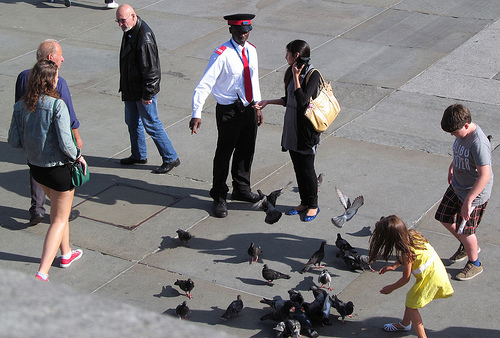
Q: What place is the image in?
A: It is at the city.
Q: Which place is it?
A: It is a city.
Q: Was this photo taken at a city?
A: Yes, it was taken in a city.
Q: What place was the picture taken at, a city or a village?
A: It was taken at a city.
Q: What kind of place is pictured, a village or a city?
A: It is a city.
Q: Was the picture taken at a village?
A: No, the picture was taken in a city.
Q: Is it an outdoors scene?
A: Yes, it is outdoors.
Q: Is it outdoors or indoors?
A: It is outdoors.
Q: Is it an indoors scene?
A: No, it is outdoors.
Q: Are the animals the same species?
A: No, there are both pigeons and birds.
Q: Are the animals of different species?
A: Yes, they are pigeons and birds.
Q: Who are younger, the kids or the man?
A: The kids are younger than the man.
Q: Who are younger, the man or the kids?
A: The kids are younger than the man.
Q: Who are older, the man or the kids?
A: The man are older than the kids.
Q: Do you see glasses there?
A: No, there are no glasses.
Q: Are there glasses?
A: No, there are no glasses.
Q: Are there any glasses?
A: No, there are no glasses.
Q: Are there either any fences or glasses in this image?
A: No, there are no glasses or fences.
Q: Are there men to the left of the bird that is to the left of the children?
A: Yes, there is a man to the left of the bird.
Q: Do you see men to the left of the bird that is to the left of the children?
A: Yes, there is a man to the left of the bird.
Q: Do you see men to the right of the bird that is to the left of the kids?
A: No, the man is to the left of the bird.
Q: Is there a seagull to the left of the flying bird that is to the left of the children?
A: No, there is a man to the left of the bird.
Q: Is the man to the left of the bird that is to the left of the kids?
A: Yes, the man is to the left of the bird.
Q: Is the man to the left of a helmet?
A: No, the man is to the left of the bird.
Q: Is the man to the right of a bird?
A: No, the man is to the left of a bird.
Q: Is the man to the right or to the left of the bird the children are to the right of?
A: The man is to the left of the bird.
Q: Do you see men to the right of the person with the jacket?
A: Yes, there is a man to the right of the person.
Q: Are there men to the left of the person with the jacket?
A: No, the man is to the right of the person.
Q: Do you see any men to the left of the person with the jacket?
A: No, the man is to the right of the person.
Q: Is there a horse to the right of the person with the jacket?
A: No, there is a man to the right of the person.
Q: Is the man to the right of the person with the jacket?
A: Yes, the man is to the right of the person.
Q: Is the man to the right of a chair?
A: No, the man is to the right of the person.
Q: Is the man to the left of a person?
A: No, the man is to the right of a person.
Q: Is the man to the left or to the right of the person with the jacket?
A: The man is to the right of the person.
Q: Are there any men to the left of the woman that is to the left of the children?
A: Yes, there is a man to the left of the woman.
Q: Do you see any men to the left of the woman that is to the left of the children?
A: Yes, there is a man to the left of the woman.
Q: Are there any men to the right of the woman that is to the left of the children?
A: No, the man is to the left of the woman.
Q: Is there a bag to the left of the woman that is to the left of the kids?
A: No, there is a man to the left of the woman.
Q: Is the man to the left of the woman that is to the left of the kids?
A: Yes, the man is to the left of the woman.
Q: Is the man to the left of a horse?
A: No, the man is to the left of the woman.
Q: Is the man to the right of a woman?
A: No, the man is to the left of a woman.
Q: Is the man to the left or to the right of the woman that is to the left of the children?
A: The man is to the left of the woman.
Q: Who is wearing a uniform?
A: The man is wearing a uniform.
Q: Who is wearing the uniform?
A: The man is wearing a uniform.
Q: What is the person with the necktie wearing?
A: The man is wearing a uniform.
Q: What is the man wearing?
A: The man is wearing a uniform.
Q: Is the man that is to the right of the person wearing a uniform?
A: Yes, the man is wearing a uniform.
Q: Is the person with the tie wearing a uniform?
A: Yes, the man is wearing a uniform.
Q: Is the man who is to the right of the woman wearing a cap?
A: No, the man is wearing a uniform.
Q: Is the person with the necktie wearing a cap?
A: No, the man is wearing a uniform.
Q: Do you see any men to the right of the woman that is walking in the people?
A: Yes, there is a man to the right of the woman.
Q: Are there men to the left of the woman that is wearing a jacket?
A: No, the man is to the right of the woman.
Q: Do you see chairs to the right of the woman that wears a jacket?
A: No, there is a man to the right of the woman.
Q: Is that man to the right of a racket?
A: No, the man is to the right of a woman.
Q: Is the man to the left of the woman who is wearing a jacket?
A: No, the man is to the right of the woman.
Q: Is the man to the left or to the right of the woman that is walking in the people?
A: The man is to the right of the woman.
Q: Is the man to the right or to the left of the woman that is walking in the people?
A: The man is to the right of the woman.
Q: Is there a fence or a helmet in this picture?
A: No, there are no fences or helmets.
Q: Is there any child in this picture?
A: Yes, there are children.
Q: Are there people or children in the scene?
A: Yes, there are children.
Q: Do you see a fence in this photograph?
A: No, there are no fences.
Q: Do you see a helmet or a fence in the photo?
A: No, there are no fences or helmets.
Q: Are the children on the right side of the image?
A: Yes, the children are on the right of the image.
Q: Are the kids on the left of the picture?
A: No, the kids are on the right of the image.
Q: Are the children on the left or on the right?
A: The children are on the right of the image.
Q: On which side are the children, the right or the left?
A: The children are on the right of the image.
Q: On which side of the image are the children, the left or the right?
A: The children are on the right of the image.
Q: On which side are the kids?
A: The kids are on the right of the image.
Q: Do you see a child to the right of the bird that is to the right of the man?
A: Yes, there are children to the right of the bird.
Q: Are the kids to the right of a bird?
A: Yes, the kids are to the right of a bird.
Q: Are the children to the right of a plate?
A: No, the children are to the right of a bird.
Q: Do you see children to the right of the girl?
A: Yes, there are children to the right of the girl.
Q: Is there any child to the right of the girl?
A: Yes, there are children to the right of the girl.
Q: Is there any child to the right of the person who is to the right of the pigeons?
A: Yes, there are children to the right of the girl.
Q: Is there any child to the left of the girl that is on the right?
A: No, the children are to the right of the girl.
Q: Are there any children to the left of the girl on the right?
A: No, the children are to the right of the girl.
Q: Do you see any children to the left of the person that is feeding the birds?
A: No, the children are to the right of the girl.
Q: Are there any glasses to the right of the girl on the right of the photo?
A: No, there are children to the right of the girl.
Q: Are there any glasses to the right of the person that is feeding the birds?
A: No, there are children to the right of the girl.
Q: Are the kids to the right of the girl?
A: Yes, the kids are to the right of the girl.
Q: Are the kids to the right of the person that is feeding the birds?
A: Yes, the kids are to the right of the girl.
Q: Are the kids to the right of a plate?
A: No, the kids are to the right of the girl.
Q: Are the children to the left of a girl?
A: No, the children are to the right of a girl.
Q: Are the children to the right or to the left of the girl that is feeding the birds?
A: The children are to the right of the girl.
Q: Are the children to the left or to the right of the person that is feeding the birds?
A: The children are to the right of the girl.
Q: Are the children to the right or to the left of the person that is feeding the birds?
A: The children are to the right of the girl.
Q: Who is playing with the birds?
A: The kids are playing with the birds.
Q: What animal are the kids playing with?
A: The kids are playing with the birds.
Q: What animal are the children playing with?
A: The kids are playing with the birds.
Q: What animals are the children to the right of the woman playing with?
A: The kids are playing with the birds.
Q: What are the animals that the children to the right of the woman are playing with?
A: The animals are birds.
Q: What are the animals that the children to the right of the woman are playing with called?
A: The animals are birds.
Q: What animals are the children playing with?
A: The kids are playing with the birds.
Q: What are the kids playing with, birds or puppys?
A: The kids are playing with birds.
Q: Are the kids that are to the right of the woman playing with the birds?
A: Yes, the children are playing with the birds.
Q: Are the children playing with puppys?
A: No, the children are playing with the birds.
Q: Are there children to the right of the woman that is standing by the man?
A: Yes, there are children to the right of the woman.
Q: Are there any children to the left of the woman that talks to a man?
A: No, the children are to the right of the woman.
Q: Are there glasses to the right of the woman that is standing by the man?
A: No, there are children to the right of the woman.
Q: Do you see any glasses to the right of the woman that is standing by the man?
A: No, there are children to the right of the woman.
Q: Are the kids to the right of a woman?
A: Yes, the kids are to the right of a woman.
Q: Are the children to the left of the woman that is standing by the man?
A: No, the children are to the right of the woman.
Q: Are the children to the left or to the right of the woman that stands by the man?
A: The children are to the right of the woman.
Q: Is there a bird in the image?
A: Yes, there are birds.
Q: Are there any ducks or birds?
A: Yes, there are birds.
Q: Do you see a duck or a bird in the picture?
A: Yes, there are birds.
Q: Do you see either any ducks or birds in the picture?
A: Yes, there are birds.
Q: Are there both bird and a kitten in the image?
A: No, there are birds but no kittens.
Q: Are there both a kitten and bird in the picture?
A: No, there are birds but no kittens.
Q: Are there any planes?
A: No, there are no planes.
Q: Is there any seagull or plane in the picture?
A: No, there are no airplanes or seagulls.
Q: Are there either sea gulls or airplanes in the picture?
A: No, there are no airplanes or sea gulls.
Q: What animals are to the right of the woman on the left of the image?
A: The animals are birds.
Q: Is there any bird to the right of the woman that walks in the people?
A: Yes, there are birds to the right of the woman.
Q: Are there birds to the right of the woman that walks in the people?
A: Yes, there are birds to the right of the woman.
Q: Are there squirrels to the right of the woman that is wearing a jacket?
A: No, there are birds to the right of the woman.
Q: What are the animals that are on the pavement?
A: The animals are birds.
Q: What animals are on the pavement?
A: The animals are birds.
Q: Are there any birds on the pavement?
A: Yes, there are birds on the pavement.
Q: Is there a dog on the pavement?
A: No, there are birds on the pavement.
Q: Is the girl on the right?
A: Yes, the girl is on the right of the image.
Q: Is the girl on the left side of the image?
A: No, the girl is on the right of the image.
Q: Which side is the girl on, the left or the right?
A: The girl is on the right of the image.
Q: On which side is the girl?
A: The girl is on the right of the image.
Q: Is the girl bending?
A: Yes, the girl is bending.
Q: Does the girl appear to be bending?
A: Yes, the girl is bending.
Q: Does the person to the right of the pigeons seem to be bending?
A: Yes, the girl is bending.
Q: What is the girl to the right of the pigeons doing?
A: The girl is bending.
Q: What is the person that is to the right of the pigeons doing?
A: The girl is bending.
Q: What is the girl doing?
A: The girl is bending.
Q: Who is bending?
A: The girl is bending.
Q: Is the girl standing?
A: No, the girl is bending.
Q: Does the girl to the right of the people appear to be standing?
A: No, the girl is bending.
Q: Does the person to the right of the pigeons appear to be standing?
A: No, the girl is bending.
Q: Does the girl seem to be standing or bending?
A: The girl is bending.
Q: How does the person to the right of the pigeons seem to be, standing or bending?
A: The girl is bending.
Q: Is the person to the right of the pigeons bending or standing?
A: The girl is bending.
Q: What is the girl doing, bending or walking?
A: The girl is bending.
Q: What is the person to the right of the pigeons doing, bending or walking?
A: The girl is bending.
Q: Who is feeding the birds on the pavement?
A: The girl is feeding the birds.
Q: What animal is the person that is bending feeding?
A: The girl is feeding the birds.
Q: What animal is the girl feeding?
A: The girl is feeding the birds.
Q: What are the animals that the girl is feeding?
A: The animals are birds.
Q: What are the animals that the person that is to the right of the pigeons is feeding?
A: The animals are birds.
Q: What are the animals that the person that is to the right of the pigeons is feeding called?
A: The animals are birds.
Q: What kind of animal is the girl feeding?
A: The girl is feeding the birds.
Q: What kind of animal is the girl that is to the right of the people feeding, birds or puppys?
A: The girl is feeding birds.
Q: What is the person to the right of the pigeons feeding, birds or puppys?
A: The girl is feeding birds.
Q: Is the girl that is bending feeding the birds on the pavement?
A: Yes, the girl is feeding the birds.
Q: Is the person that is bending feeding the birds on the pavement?
A: Yes, the girl is feeding the birds.